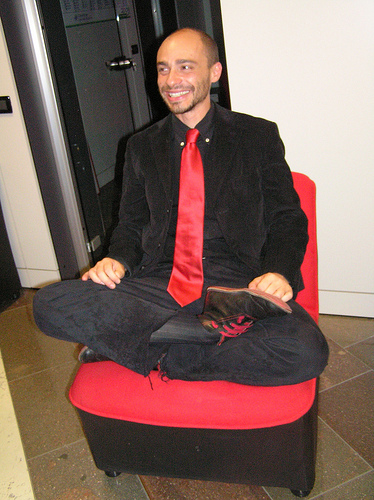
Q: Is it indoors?
A: Yes, it is indoors.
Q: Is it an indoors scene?
A: Yes, it is indoors.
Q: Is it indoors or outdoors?
A: It is indoors.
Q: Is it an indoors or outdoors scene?
A: It is indoors.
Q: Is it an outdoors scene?
A: No, it is indoors.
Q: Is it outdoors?
A: No, it is indoors.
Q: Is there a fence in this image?
A: No, there are no fences.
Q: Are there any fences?
A: No, there are no fences.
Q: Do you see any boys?
A: No, there are no boys.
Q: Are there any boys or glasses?
A: No, there are no boys or glasses.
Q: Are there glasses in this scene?
A: No, there are no glasses.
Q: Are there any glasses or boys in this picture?
A: No, there are no glasses or boys.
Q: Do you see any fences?
A: No, there are no fences.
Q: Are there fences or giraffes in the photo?
A: No, there are no fences or giraffes.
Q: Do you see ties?
A: Yes, there is a tie.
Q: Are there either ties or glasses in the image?
A: Yes, there is a tie.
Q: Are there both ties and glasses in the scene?
A: No, there is a tie but no glasses.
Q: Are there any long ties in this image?
A: Yes, there is a long tie.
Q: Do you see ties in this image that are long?
A: Yes, there is a tie that is long.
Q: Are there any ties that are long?
A: Yes, there is a tie that is long.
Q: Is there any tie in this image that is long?
A: Yes, there is a tie that is long.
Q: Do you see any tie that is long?
A: Yes, there is a tie that is long.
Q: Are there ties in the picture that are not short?
A: Yes, there is a long tie.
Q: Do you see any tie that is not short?
A: Yes, there is a long tie.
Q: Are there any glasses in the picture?
A: No, there are no glasses.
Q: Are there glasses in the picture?
A: No, there are no glasses.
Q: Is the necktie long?
A: Yes, the necktie is long.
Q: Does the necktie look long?
A: Yes, the necktie is long.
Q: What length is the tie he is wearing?
A: The necktie is long.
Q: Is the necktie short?
A: No, the necktie is long.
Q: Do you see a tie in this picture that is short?
A: No, there is a tie but it is long.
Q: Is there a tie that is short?
A: No, there is a tie but it is long.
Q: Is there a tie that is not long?
A: No, there is a tie but it is long.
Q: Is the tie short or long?
A: The tie is long.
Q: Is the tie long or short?
A: The tie is long.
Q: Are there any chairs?
A: Yes, there is a chair.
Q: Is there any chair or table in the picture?
A: Yes, there is a chair.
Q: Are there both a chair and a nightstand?
A: No, there is a chair but no nightstands.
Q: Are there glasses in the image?
A: No, there are no glasses.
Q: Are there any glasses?
A: No, there are no glasses.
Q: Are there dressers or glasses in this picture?
A: No, there are no glasses or dressers.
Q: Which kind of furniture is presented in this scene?
A: The furniture is a chair.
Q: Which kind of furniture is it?
A: The piece of furniture is a chair.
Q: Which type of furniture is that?
A: This is a chair.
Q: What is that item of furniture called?
A: This is a chair.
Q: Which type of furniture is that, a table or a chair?
A: This is a chair.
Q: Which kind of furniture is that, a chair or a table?
A: This is a chair.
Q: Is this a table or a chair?
A: This is a chair.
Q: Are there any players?
A: No, there are no players.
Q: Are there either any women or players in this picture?
A: No, there are no players or women.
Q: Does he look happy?
A: Yes, the man is happy.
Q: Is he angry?
A: No, the man is happy.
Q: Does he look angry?
A: No, the man is happy.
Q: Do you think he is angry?
A: No, the man is happy.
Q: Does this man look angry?
A: No, the man is happy.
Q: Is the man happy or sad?
A: The man is happy.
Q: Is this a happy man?
A: Yes, this is a happy man.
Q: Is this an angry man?
A: No, this is a happy man.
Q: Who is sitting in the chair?
A: The man is sitting in the chair.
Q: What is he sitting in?
A: The man is sitting in the chair.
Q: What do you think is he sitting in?
A: The man is sitting in the chair.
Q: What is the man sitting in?
A: The man is sitting in the chair.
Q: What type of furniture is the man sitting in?
A: The man is sitting in the chair.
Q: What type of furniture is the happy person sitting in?
A: The man is sitting in the chair.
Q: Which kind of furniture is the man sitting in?
A: The man is sitting in the chair.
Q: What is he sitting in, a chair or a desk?
A: The man is sitting in a chair.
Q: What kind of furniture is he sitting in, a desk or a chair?
A: The man is sitting in a chair.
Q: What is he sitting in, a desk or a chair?
A: The man is sitting in a chair.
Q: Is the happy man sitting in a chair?
A: Yes, the man is sitting in a chair.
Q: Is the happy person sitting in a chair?
A: Yes, the man is sitting in a chair.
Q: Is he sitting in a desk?
A: No, the man is sitting in a chair.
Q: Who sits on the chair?
A: The man sits on the chair.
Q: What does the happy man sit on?
A: The man sits on the chair.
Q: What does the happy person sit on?
A: The man sits on the chair.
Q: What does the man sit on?
A: The man sits on the chair.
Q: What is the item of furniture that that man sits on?
A: The piece of furniture is a chair.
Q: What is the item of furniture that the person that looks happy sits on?
A: The piece of furniture is a chair.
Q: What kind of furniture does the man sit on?
A: The man sits on the chair.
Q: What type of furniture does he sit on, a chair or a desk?
A: The man sits on a chair.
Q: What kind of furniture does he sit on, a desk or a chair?
A: The man sits on a chair.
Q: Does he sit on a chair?
A: Yes, the man sits on a chair.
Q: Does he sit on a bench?
A: No, the man sits on a chair.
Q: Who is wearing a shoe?
A: The man is wearing a shoe.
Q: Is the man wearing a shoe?
A: Yes, the man is wearing a shoe.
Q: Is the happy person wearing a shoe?
A: Yes, the man is wearing a shoe.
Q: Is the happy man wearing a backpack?
A: No, the man is wearing a shoe.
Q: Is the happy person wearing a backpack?
A: No, the man is wearing a shoe.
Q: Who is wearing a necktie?
A: The man is wearing a necktie.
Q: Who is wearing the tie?
A: The man is wearing a necktie.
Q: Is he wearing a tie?
A: Yes, the man is wearing a tie.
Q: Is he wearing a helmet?
A: No, the man is wearing a tie.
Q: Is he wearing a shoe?
A: Yes, the man is wearing a shoe.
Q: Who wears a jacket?
A: The man wears a jacket.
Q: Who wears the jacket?
A: The man wears a jacket.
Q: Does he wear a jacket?
A: Yes, the man wears a jacket.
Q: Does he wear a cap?
A: No, the man wears a jacket.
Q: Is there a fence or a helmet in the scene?
A: No, there are no fences or helmets.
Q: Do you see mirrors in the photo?
A: No, there are no mirrors.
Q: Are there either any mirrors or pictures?
A: No, there are no mirrors or pictures.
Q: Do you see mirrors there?
A: No, there are no mirrors.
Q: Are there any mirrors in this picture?
A: No, there are no mirrors.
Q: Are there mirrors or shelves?
A: No, there are no mirrors or shelves.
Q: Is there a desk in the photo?
A: No, there are no desks.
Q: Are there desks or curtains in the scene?
A: No, there are no desks or curtains.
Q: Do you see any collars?
A: Yes, there is a collar.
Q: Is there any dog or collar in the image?
A: Yes, there is a collar.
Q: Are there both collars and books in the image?
A: No, there is a collar but no books.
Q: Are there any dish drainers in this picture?
A: No, there are no dish drainers.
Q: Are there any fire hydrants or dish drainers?
A: No, there are no dish drainers or fire hydrants.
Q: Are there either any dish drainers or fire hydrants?
A: No, there are no dish drainers or fire hydrants.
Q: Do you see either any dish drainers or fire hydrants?
A: No, there are no dish drainers or fire hydrants.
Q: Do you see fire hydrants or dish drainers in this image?
A: No, there are no dish drainers or fire hydrants.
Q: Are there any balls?
A: No, there are no balls.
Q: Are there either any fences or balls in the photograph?
A: No, there are no balls or fences.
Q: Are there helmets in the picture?
A: No, there are no helmets.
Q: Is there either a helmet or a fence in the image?
A: No, there are no helmets or fences.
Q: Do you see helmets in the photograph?
A: No, there are no helmets.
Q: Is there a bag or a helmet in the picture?
A: No, there are no helmets or bags.